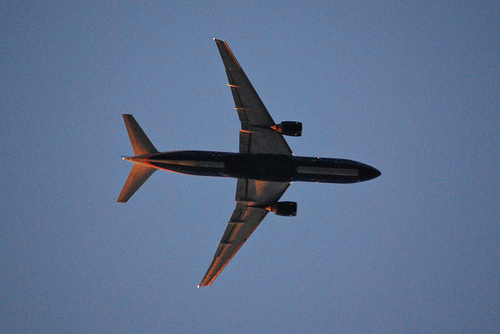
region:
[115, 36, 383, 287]
an airplane flying in the blue sky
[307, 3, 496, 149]
the clear blue sky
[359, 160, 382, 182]
the nose of an airplane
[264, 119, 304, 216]
two engines on the airplane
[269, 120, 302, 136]
an engine on the airplane's left wing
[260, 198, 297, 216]
an engine on the right wing of the airplane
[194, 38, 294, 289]
two wings on the airplane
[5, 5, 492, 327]
an airplane in the sky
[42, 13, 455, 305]
an airline jet in the air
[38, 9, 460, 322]
a black and silver airplane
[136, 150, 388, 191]
bottom of large airplane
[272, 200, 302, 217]
engine on right wing of plane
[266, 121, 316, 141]
engine on left wing of plane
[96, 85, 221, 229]
tail of big airplane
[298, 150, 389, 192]
white area under big airplane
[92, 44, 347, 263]
airplane is flying eastward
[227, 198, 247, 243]
ridges under right wing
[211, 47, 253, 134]
ridges under left wing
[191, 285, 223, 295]
light on the end of wing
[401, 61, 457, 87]
sky is violet blue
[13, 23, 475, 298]
airplane flying against solid blue sky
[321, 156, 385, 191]
pointed nose on front on plane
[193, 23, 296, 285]
wings curving toward back of plane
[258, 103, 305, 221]
dark and short cylinders attached to wings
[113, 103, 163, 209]
flared smaller wings on end of plane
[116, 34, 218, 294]
small white lights on wing and tail tips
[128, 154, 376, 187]
faint line down center of plane body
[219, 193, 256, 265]
ridges partly across wings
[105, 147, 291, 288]
reddish light reflecting off part of plane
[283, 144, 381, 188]
two points of outer light between nose and wing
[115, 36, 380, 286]
a commercial jet in flight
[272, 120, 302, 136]
the starboard turbine engine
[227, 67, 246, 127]
the aileron on the wing for lift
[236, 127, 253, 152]
the airplane wing flaps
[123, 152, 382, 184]
the jet airplanes fuselage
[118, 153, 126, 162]
the tail navigation lights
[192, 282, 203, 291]
the port wing navigation light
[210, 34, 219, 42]
the starboard wing navigation light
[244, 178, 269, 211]
a reflection of light on the wing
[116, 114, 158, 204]
the tail of the jet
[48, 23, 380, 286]
the underside of an airplane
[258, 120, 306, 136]
an engine sticks out from the wing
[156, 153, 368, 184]
two white stripes go down the center on the black plane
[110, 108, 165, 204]
the sun makes the plane tail glow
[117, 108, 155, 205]
tail wings are smaller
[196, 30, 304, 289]
the larger main wings of the plane hold the engines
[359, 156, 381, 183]
thge plane nose is tapered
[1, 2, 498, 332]
an all blue sky with no clouds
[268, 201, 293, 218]
the engine is black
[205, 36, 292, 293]
wings lit the sun are grey underneath